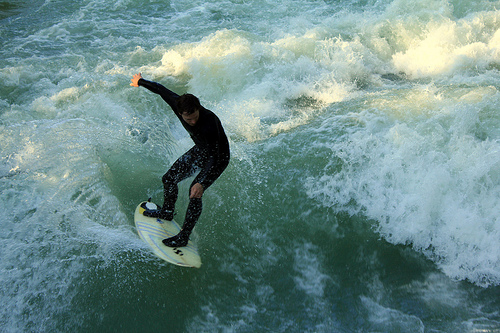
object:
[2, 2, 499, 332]
ocean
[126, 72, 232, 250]
man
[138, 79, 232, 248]
wetsuit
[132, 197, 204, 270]
surfboard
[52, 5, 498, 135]
wave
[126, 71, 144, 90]
hand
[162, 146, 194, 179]
thigh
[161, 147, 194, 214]
leg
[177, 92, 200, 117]
hair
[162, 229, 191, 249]
foot